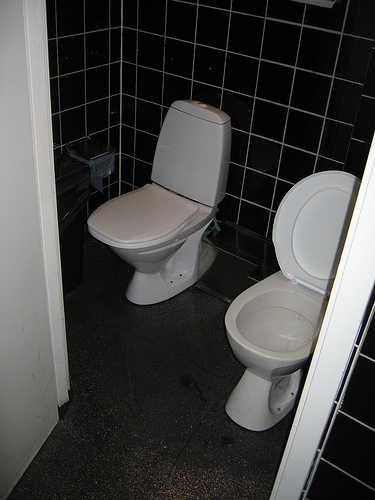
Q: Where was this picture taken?
A: Bathroom.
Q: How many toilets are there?
A: Two.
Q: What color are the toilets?
A: White.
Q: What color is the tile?
A: Black.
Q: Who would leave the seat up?
A: A man.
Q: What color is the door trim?
A: White.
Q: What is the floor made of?
A: Concrete.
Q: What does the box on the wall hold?
A: Toilet paper.